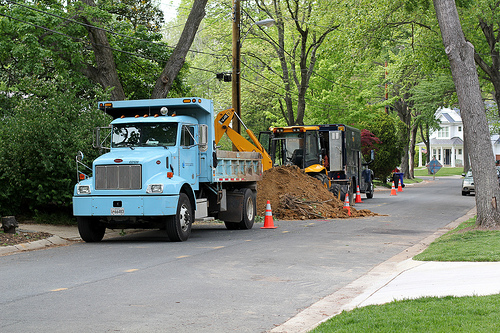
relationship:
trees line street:
[0, 0, 213, 226] [0, 174, 474, 331]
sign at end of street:
[424, 153, 445, 177] [0, 174, 474, 331]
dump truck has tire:
[67, 94, 264, 242] [167, 193, 194, 242]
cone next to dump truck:
[260, 196, 277, 232] [67, 94, 264, 242]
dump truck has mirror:
[67, 94, 264, 242] [184, 124, 210, 151]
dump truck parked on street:
[67, 94, 264, 242] [0, 174, 474, 331]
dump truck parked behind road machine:
[67, 94, 264, 242] [215, 106, 376, 200]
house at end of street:
[415, 105, 500, 170] [0, 174, 474, 331]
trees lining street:
[0, 0, 213, 226] [0, 174, 474, 331]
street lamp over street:
[239, 18, 275, 55] [0, 174, 474, 331]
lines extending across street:
[2, 1, 357, 110] [0, 174, 474, 331]